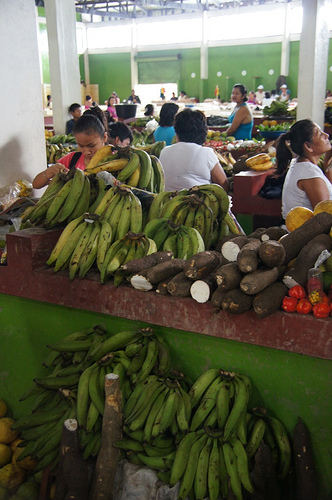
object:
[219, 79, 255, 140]
person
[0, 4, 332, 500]
market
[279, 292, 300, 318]
peppers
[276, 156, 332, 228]
shirt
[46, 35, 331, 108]
wall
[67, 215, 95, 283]
bananas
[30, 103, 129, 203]
woman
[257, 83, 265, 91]
hat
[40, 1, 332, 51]
sun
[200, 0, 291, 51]
windows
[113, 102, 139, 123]
bucket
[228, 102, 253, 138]
top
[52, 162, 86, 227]
bananas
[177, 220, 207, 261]
bananas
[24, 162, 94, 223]
bunch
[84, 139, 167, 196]
bunch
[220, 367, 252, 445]
bananas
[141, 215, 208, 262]
bunch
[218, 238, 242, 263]
roots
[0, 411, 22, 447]
melons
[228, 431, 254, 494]
plantains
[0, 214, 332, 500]
wall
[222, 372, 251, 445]
plantains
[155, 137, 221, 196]
shirt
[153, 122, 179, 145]
top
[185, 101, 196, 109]
bowl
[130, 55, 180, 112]
door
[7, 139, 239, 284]
display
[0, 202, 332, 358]
table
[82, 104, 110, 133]
pony tail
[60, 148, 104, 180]
shirt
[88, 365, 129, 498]
stick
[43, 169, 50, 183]
bracelet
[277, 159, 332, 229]
top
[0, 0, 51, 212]
walls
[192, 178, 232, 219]
banana